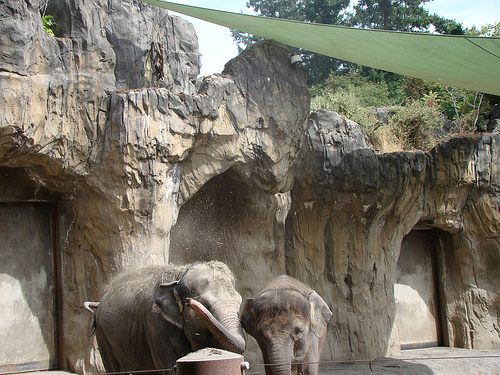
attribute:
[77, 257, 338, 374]
elephants — standing, gray, 2, eating, paired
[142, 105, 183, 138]
rocks — brown, cement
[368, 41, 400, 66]
canopy — green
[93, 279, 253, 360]
elephant — big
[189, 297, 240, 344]
trunk — long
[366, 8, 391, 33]
trees — green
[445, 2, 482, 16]
sky — blue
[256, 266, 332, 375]
elephant — smaller, facing, small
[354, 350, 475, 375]
fence — metal, wire